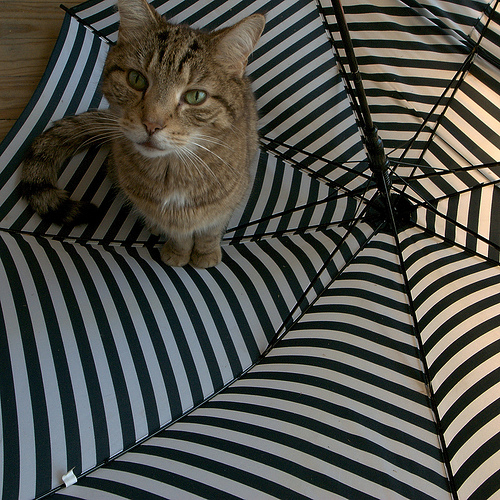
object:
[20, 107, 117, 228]
tail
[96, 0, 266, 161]
head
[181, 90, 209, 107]
eye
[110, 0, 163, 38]
ear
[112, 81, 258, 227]
torso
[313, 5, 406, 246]
metal pole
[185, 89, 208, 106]
green eye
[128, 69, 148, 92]
green eye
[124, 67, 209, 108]
eyes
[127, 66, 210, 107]
eyeballs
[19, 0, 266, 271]
cat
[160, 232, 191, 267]
paw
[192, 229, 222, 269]
paw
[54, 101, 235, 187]
white whiskers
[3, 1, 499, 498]
umbrella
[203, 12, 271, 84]
ear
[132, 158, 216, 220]
stripes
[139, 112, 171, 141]
nose